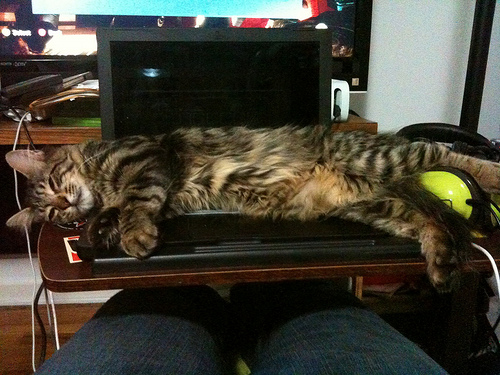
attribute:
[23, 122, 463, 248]
cat — striped, sleeping, happy, resting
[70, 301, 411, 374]
jeans — blue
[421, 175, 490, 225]
headphones — green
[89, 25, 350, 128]
laptop — black, off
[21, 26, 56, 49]
tv — distant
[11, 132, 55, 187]
ear — pink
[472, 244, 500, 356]
cable — white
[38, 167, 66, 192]
eye — half opened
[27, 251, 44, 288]
wire — white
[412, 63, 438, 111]
wall — white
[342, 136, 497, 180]
leg — back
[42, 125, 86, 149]
shelf — tan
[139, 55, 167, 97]
reflection — light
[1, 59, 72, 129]
desk — brown, wood, messy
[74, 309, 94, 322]
floors — hardwood